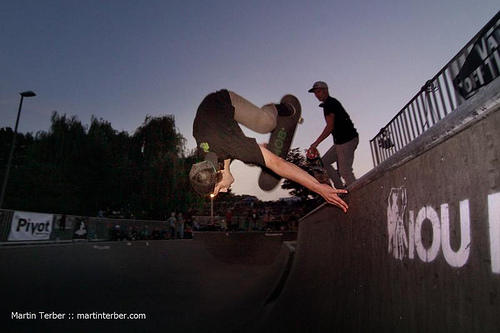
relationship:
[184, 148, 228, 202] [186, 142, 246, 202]
hat on head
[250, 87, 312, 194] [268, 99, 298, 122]
skateboard under feet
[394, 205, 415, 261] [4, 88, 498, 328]
letters on ramp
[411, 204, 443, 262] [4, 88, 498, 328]
letters on ramp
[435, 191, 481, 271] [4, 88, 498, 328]
letters on ramp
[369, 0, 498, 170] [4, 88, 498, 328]
rail on top of ramp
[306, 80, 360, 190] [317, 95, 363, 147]
boy wearing shirt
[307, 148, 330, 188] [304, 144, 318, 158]
skateboard in hand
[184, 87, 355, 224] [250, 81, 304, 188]
boy on skateboard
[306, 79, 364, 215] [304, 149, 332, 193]
boy holding skateboard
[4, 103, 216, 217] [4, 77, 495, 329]
trees by park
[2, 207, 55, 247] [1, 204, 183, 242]
banner on fence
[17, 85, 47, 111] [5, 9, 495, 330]
light in park